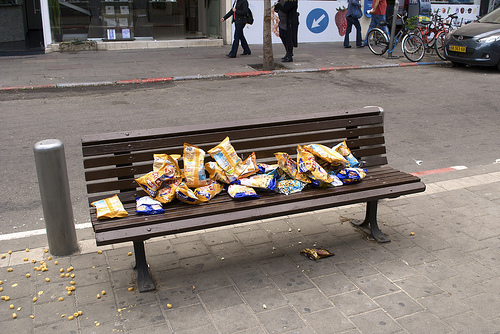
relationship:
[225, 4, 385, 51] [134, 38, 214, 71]
people on sidewalk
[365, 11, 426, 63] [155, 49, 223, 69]
bicycles parked on sidewalk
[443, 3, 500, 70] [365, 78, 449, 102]
car on road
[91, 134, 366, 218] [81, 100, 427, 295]
bags on bench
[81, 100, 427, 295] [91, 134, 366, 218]
bench with bags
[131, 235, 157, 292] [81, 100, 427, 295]
bottom of bench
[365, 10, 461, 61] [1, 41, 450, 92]
bicycles parked on sidewalk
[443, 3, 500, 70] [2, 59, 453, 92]
car parked at curb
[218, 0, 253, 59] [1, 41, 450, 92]
pedestrian walking down sidewalk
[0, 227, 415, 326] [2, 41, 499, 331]
cheese pops scattered on ground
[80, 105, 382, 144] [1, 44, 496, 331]
bench edge with background of street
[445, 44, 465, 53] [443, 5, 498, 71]
tag on car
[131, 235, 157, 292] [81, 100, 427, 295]
bottom on bench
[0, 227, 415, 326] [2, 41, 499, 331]
cheese pops on ground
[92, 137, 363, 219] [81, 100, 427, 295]
chips on bench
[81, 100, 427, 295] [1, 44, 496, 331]
bench beside street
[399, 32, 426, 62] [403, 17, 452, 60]
tire on bicycles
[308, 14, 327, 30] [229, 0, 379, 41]
arrow on wall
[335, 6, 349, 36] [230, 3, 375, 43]
strawberry on wall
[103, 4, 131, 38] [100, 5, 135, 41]
papers on stand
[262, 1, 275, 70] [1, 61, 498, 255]
tree beside street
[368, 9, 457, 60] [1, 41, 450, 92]
bicycles on sidewalk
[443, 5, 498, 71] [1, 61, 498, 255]
car parked on street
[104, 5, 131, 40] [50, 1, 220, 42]
labels in window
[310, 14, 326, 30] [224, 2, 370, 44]
arrow on wall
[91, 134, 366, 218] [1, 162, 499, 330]
bags on sidewalk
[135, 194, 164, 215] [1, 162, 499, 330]
bag on sidewalk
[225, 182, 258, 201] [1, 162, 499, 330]
bag on sidewalk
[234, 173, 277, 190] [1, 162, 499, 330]
bag on sidewalk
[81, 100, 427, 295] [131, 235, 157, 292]
bench has bottom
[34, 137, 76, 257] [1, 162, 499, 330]
pole on sidewalk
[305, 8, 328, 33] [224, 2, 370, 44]
sign on wall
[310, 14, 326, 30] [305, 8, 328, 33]
arrow on sign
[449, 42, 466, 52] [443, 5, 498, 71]
license plate on car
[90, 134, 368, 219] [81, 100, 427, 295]
packets on bench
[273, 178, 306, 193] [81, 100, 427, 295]
packet on bench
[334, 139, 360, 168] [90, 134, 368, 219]
packet on packets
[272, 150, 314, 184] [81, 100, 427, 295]
packet on bench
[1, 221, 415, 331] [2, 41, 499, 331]
cheese pops fallen on ground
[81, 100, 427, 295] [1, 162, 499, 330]
bench on sidewalk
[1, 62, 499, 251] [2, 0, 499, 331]
road in town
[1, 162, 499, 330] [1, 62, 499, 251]
sidewalk next to road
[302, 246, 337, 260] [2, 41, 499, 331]
pack on ground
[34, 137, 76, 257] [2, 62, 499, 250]
pole on roadside